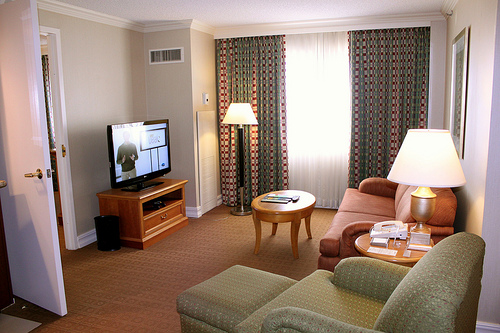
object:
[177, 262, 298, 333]
ottoman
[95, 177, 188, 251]
wooden stand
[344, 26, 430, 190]
curtains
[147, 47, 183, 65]
vent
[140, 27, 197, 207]
wall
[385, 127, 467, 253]
lamp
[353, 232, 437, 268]
table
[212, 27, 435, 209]
window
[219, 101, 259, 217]
lamp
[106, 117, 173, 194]
tv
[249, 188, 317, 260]
table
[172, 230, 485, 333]
chair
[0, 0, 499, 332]
living room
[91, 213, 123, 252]
black garbage-can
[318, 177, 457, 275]
sofa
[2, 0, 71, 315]
open door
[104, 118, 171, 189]
housing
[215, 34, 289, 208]
curtain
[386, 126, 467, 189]
lamp shade